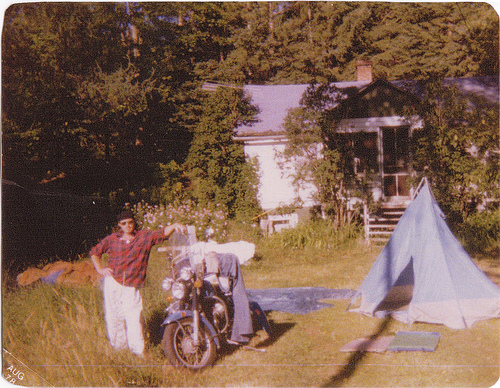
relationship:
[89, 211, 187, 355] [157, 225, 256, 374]
man next to bike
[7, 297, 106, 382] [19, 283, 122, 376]
grass and grass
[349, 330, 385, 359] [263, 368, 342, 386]
mat on grass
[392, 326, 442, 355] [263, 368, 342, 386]
mat on grass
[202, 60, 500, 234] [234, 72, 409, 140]
building with roof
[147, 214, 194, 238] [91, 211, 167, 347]
hand of man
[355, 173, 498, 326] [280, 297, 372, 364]
tent on ground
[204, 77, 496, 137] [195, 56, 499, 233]
roof of building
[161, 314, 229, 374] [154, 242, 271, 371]
wheel of bike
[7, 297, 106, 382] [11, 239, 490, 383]
grass on ground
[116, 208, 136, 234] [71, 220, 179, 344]
head on man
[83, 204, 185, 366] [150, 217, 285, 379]
man standing near cycle